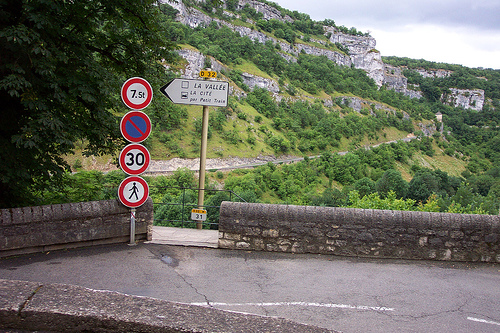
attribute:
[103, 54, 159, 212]
sign — red, white, round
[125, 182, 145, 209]
man — walking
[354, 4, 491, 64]
sky — cloudy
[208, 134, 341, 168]
road — winding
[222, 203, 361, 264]
fence — brick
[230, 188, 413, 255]
wall — brick, stones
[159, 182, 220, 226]
rail — metal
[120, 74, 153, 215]
signs — together, round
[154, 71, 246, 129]
sign — white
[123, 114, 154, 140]
sign — no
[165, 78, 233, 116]
sign — arrow